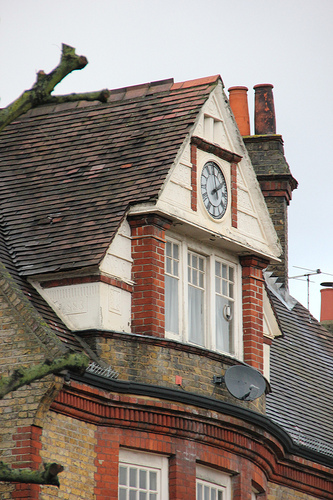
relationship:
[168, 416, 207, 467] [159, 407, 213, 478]
discoloration on brick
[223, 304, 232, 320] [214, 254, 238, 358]
object attached to window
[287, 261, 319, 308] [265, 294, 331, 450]
antenna on roof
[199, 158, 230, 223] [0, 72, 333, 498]
clock in house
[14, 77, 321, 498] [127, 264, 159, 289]
house with brick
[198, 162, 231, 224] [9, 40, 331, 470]
clock on house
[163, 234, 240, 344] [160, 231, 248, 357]
set of windows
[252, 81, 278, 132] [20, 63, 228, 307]
chimney with top